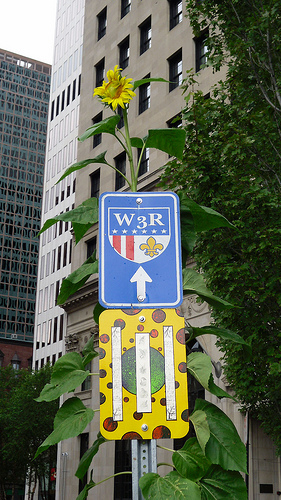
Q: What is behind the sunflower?
A: A large building.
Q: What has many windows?
A: Tall gray building.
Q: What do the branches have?
A: Green leaves.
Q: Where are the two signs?
A: On a pole.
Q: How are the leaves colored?
A: Green.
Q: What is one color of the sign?
A: Yellow.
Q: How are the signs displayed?
A: Colorfully.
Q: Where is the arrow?
A: On the blue sign.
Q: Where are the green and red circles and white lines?
A: On the yellow sign.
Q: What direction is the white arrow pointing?
A: Straight ahead.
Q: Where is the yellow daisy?
A: Top of the signs.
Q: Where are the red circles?
A: On the yellow sign.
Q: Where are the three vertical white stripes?
A: Yellow sign.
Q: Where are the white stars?
A: Under the W3R.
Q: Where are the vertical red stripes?
A: Under the white stars.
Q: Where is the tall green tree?
A: Right of the signs.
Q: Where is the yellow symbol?
A: Right of the red stripes.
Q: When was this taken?
A: During the day.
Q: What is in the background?
A: Skyscrapers.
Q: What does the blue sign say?
A: W3R.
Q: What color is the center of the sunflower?
A: Orange.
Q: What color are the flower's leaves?
A: Green.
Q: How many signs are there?
A: Two.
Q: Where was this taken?
A: In a plaza.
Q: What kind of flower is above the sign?
A: A sunflower.